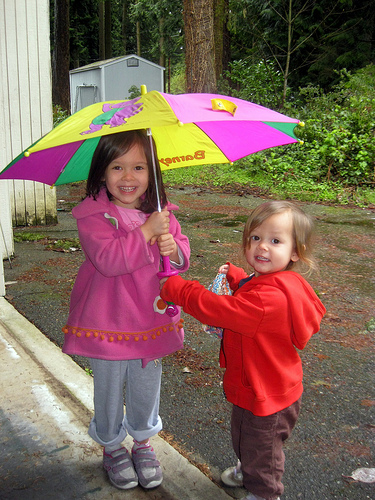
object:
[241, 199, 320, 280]
hair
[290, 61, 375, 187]
green trees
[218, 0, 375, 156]
trees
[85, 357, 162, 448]
pants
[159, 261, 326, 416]
jacket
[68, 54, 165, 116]
shed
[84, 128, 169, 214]
hair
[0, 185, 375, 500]
ground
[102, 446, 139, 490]
athletic shoes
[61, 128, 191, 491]
girl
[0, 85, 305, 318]
umbrella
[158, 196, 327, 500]
child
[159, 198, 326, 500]
kid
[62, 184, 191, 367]
coat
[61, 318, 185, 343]
fringe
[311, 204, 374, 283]
moss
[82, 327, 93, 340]
pom pom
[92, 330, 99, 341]
pom pom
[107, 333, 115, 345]
pom pom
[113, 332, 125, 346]
pom pom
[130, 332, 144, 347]
pom pom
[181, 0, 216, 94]
trunk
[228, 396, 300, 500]
pants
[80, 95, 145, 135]
barney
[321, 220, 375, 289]
puddles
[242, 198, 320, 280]
head